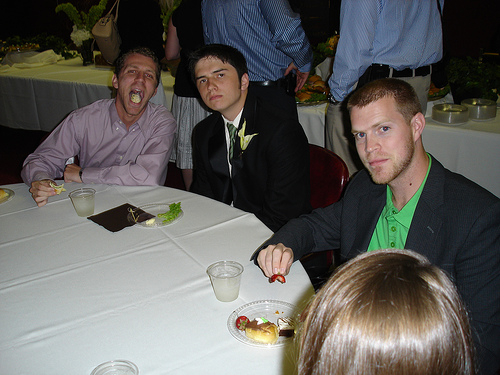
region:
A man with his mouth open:
[23, 44, 175, 207]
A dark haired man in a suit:
[186, 44, 324, 284]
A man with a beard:
[252, 76, 499, 371]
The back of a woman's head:
[294, 250, 476, 373]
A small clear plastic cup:
[207, 258, 246, 301]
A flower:
[234, 117, 260, 159]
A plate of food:
[226, 299, 298, 344]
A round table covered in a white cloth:
[0, 179, 315, 372]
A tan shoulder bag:
[91, 2, 126, 67]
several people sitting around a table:
[13, 23, 471, 368]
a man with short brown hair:
[342, 68, 441, 192]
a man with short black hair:
[186, 39, 256, 125]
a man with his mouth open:
[105, 43, 161, 118]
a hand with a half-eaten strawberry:
[254, 241, 296, 288]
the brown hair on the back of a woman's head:
[294, 240, 481, 374]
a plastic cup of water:
[199, 253, 249, 310]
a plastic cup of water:
[66, 186, 102, 217]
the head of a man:
[341, 76, 438, 186]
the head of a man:
[183, 45, 257, 116]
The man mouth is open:
[113, 75, 158, 119]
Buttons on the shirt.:
[383, 207, 395, 245]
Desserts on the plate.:
[241, 304, 282, 339]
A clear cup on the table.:
[203, 251, 264, 303]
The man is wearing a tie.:
[212, 117, 252, 177]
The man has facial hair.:
[390, 149, 415, 182]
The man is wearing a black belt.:
[379, 59, 439, 82]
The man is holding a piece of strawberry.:
[258, 263, 286, 286]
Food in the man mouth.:
[124, 93, 140, 103]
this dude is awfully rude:
[103, 39, 168, 129]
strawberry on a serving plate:
[231, 310, 251, 334]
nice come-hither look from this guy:
[338, 73, 435, 190]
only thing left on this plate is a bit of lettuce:
[152, 199, 189, 230]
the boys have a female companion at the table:
[288, 240, 487, 374]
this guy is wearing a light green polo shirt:
[356, 146, 438, 261]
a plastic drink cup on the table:
[201, 257, 251, 304]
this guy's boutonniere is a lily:
[228, 115, 265, 177]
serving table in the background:
[2, 0, 499, 133]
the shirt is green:
[370, 195, 415, 262]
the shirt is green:
[371, 189, 451, 306]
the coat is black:
[171, 110, 313, 227]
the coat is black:
[175, 107, 318, 237]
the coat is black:
[167, 105, 318, 235]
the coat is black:
[177, 114, 305, 216]